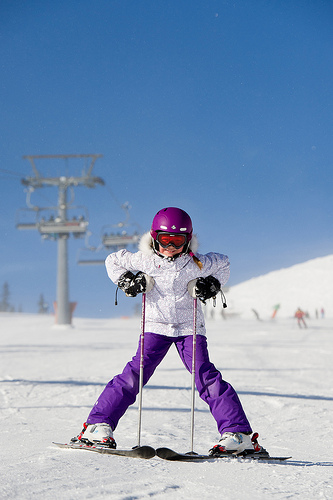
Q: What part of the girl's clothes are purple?
A: The snow pants.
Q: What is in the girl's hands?
A: Two ski poles.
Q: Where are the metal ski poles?
A: In the girl's hands.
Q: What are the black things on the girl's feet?
A: Skis.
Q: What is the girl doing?
A: Skiing.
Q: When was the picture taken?
A: During the daytime.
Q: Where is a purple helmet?
A: On girl's head.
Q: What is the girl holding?
A: Ski poles.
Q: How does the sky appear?
A: Blue and clear.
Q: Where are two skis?
A: Under girl's feet.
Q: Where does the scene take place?
A: On a ski slope.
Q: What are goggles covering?
A: Girl's eyes.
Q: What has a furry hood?
A: White jacket.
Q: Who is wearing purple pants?
A: A girl.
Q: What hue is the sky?
A: Blue.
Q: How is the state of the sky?
A: Clear.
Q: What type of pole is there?
A: Electric pole.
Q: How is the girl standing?
A: Pigeon toed.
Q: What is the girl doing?
A: Posing.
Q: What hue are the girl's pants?
A: Purple.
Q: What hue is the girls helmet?
A: Purple.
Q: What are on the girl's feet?
A: Skis.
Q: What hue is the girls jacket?
A: Faded purple.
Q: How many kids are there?
A: One.